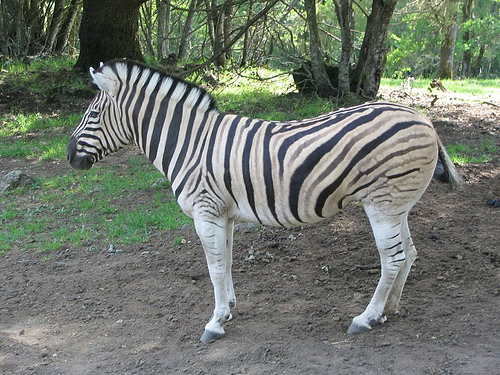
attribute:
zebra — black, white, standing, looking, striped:
[68, 54, 468, 345]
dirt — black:
[0, 89, 498, 370]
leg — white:
[194, 216, 231, 345]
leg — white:
[226, 223, 237, 308]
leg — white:
[348, 208, 403, 332]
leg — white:
[388, 218, 415, 313]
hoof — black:
[200, 327, 225, 346]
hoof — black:
[345, 318, 369, 336]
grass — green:
[6, 55, 497, 253]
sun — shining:
[224, 63, 300, 91]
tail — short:
[436, 137, 462, 194]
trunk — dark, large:
[73, 3, 146, 70]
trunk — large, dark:
[209, 1, 277, 62]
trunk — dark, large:
[304, 1, 330, 95]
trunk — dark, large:
[333, 3, 358, 87]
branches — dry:
[240, 11, 292, 51]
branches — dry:
[150, 3, 208, 45]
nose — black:
[64, 137, 87, 170]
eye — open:
[87, 110, 104, 121]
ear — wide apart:
[82, 64, 119, 87]